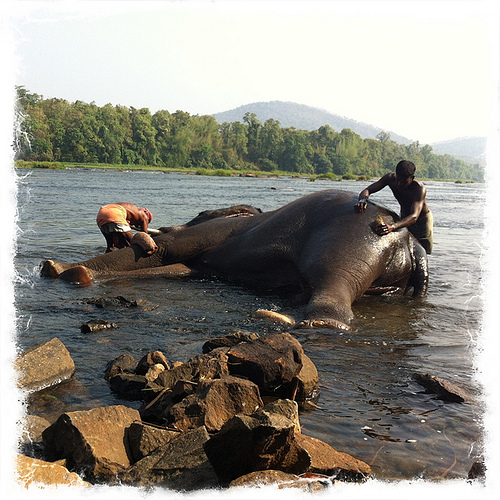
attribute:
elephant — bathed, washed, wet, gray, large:
[35, 177, 442, 345]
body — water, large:
[19, 171, 474, 318]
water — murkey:
[24, 177, 471, 317]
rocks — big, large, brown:
[22, 289, 472, 455]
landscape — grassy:
[14, 86, 489, 170]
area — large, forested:
[24, 82, 495, 173]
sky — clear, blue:
[15, 0, 491, 160]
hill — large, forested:
[186, 88, 391, 141]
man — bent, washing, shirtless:
[92, 202, 156, 260]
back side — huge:
[354, 226, 426, 308]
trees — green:
[16, 84, 485, 182]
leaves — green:
[22, 85, 482, 177]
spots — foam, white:
[111, 297, 410, 408]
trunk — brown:
[157, 223, 186, 231]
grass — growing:
[24, 149, 485, 172]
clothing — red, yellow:
[95, 199, 135, 237]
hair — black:
[398, 158, 419, 178]